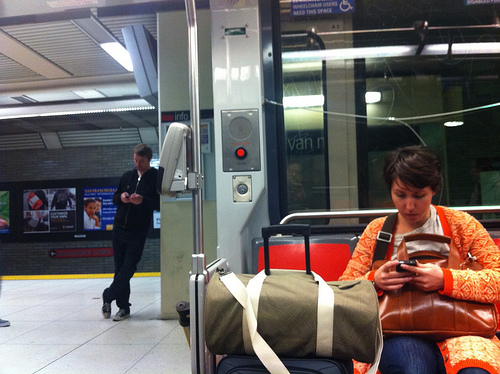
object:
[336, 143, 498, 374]
woman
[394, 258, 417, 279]
cellphone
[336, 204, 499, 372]
sweater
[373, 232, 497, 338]
purse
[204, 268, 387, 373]
dufflebag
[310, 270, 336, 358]
straps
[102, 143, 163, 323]
man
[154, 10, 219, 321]
wall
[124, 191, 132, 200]
cellphone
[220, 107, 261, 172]
cover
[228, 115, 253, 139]
speaker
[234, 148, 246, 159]
button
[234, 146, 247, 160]
trim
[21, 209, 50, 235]
advertisements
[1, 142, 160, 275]
wall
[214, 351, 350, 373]
suitcase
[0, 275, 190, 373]
ground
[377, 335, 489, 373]
jeans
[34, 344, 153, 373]
tile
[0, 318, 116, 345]
tile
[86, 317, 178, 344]
tile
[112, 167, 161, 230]
jacket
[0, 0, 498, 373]
station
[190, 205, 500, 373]
bench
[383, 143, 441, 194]
hair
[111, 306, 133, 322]
sneakers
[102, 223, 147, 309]
pants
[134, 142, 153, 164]
hair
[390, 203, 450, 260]
shirt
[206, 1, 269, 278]
pillar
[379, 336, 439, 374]
lap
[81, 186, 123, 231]
billboard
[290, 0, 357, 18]
handicap sign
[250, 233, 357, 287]
seat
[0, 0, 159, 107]
ceiling